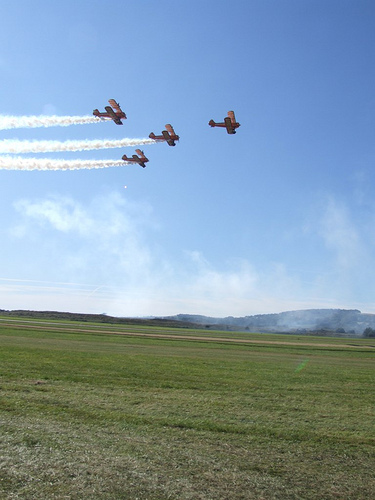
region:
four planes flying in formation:
[69, 68, 306, 201]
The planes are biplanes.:
[46, 50, 302, 210]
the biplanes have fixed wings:
[70, 52, 315, 255]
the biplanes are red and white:
[82, 72, 298, 207]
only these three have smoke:
[7, 84, 184, 182]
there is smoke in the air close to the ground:
[30, 188, 373, 342]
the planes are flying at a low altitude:
[15, 55, 267, 203]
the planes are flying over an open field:
[7, 73, 282, 189]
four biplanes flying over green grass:
[5, 71, 280, 200]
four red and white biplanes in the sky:
[8, 77, 318, 199]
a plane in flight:
[92, 97, 127, 125]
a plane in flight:
[150, 121, 178, 148]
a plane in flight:
[118, 149, 148, 167]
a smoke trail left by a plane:
[0, 112, 111, 130]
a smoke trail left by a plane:
[1, 137, 154, 149]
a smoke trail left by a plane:
[0, 154, 133, 170]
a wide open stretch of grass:
[0, 315, 372, 499]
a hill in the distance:
[147, 307, 373, 335]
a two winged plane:
[207, 109, 239, 135]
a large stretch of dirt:
[1, 318, 371, 350]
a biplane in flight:
[208, 110, 238, 134]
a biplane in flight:
[148, 123, 179, 147]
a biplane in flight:
[120, 147, 148, 167]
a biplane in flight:
[93, 98, 127, 126]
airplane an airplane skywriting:
[0, 146, 152, 169]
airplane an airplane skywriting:
[0, 122, 181, 154]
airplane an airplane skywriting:
[2, 97, 127, 126]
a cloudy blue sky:
[0, 2, 371, 317]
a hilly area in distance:
[118, 308, 374, 339]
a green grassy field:
[0, 315, 373, 498]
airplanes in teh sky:
[65, 40, 362, 212]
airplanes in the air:
[68, 44, 364, 325]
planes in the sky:
[73, 99, 367, 244]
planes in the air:
[76, 66, 354, 269]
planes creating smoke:
[21, 72, 339, 252]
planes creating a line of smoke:
[33, 81, 373, 257]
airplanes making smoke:
[75, 33, 321, 269]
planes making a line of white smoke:
[14, 65, 350, 247]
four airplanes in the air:
[73, 68, 327, 206]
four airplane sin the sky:
[70, 71, 312, 238]